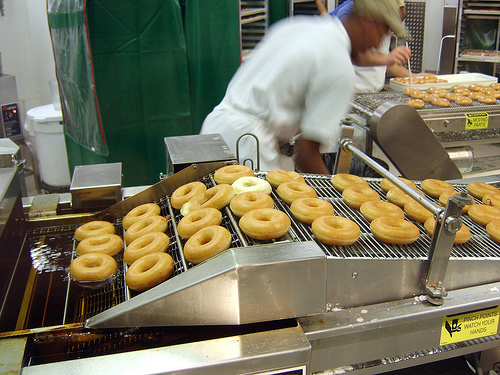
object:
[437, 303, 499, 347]
label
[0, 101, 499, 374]
machine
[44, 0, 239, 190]
tent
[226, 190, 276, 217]
donut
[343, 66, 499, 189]
machine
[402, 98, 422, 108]
donuts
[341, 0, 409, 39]
hat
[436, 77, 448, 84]
donuts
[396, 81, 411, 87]
donuts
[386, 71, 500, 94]
container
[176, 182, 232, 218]
donuts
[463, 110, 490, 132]
sticker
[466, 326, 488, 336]
text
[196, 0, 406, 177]
man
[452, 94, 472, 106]
donuts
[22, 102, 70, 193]
trashcan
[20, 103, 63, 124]
lid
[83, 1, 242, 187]
curtain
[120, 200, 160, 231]
donuts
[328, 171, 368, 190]
donuts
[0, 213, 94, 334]
oil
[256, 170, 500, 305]
racks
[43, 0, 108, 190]
cover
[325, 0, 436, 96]
man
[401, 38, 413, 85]
spoon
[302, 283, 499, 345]
glaze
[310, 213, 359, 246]
donut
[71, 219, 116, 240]
donut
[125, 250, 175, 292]
donut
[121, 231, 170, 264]
donut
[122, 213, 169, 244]
donut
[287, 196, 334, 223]
donut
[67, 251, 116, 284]
doughnut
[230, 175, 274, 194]
doughnut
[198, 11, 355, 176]
outfit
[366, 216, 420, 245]
donut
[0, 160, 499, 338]
belt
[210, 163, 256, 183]
donut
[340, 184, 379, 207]
donut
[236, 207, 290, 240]
donut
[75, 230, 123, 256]
donut